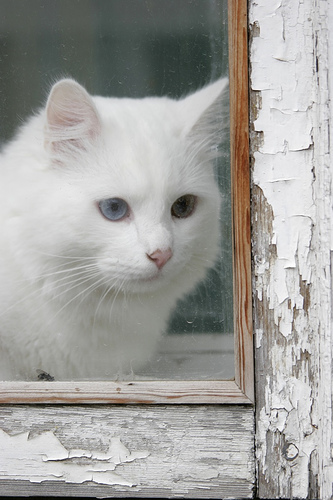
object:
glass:
[0, 0, 235, 382]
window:
[0, 0, 251, 403]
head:
[17, 76, 230, 291]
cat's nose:
[145, 246, 173, 270]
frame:
[245, 0, 332, 499]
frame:
[1, 403, 260, 499]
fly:
[35, 368, 55, 380]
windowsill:
[0, 380, 254, 403]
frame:
[1, 0, 253, 408]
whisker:
[17, 225, 142, 338]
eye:
[97, 193, 130, 222]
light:
[95, 136, 215, 215]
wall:
[138, 90, 181, 122]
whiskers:
[13, 247, 135, 330]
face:
[52, 149, 223, 292]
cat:
[0, 73, 231, 380]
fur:
[97, 103, 179, 167]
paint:
[255, 0, 332, 500]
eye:
[172, 194, 198, 217]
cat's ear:
[44, 77, 100, 166]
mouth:
[116, 269, 167, 285]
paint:
[0, 404, 325, 496]